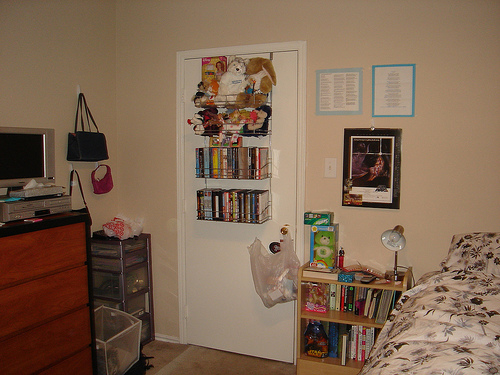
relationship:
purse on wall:
[67, 92, 111, 163] [1, 0, 118, 237]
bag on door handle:
[248, 224, 302, 308] [282, 223, 292, 235]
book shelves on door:
[195, 146, 274, 224] [183, 48, 300, 364]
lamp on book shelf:
[381, 224, 407, 281] [296, 259, 414, 373]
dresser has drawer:
[0, 210, 97, 374] [0, 219, 88, 288]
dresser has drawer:
[0, 210, 97, 374] [0, 262, 90, 338]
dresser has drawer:
[0, 210, 97, 374] [0, 304, 93, 374]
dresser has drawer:
[0, 210, 97, 374] [35, 344, 95, 374]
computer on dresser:
[0, 126, 57, 193] [0, 210, 97, 374]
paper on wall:
[316, 66, 364, 117] [115, 1, 498, 365]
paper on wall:
[371, 63, 416, 118] [115, 1, 498, 365]